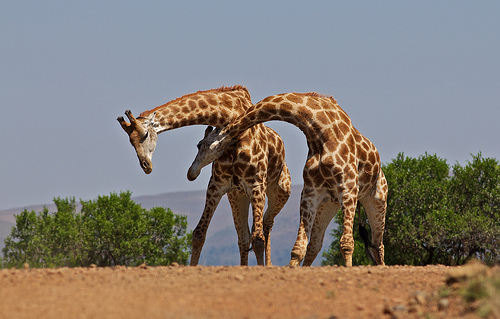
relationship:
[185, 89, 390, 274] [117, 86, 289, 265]
giraffe playing with giraffe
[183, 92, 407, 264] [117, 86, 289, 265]
giraffe playing with giraffe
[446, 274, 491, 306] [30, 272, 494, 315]
grass up in dirt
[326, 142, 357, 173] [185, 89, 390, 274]
spots are on giraffe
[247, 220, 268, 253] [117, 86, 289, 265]
knee on giraffe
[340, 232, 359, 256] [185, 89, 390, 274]
knee on giraffe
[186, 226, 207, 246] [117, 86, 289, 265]
knee on a giraffe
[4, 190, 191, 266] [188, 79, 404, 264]
tree tops to left of giraffe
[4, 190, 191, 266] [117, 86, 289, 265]
tree tops to left of giraffe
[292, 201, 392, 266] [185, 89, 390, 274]
legs of giraffe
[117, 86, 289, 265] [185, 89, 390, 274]
giraffe next to giraffe